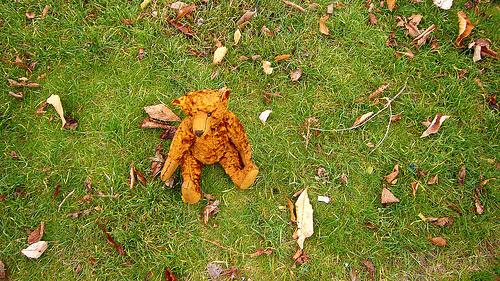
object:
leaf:
[46, 94, 67, 127]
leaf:
[212, 47, 229, 67]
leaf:
[235, 12, 255, 26]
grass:
[0, 0, 499, 281]